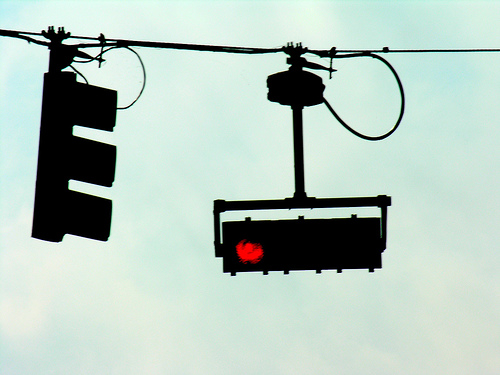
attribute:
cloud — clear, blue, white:
[1, 213, 150, 335]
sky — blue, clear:
[1, 0, 500, 373]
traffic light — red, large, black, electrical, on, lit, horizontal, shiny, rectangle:
[221, 216, 384, 275]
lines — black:
[323, 53, 405, 141]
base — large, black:
[212, 196, 392, 214]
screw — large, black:
[299, 42, 304, 48]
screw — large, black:
[290, 41, 295, 47]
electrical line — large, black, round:
[0, 28, 499, 53]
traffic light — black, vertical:
[32, 72, 120, 242]